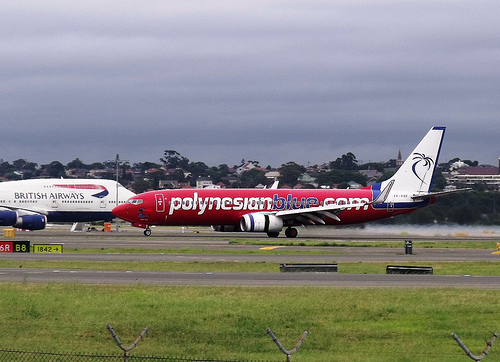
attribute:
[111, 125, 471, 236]
plane — red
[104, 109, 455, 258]
airplane — white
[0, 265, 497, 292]
runway — grassy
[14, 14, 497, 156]
sky — cloudy, overcast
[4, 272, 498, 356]
grass — green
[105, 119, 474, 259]
airplane — white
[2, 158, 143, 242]
airplane — white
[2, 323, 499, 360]
fence — metal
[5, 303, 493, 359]
barbed fence — gray, metal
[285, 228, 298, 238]
tire — black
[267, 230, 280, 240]
tire — black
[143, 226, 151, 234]
tire — black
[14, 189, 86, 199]
lettering — black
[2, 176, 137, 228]
airplane — white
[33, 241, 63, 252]
sign — yellow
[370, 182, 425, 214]
stripe — red, blue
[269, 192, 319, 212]
word — blue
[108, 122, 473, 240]
airplane — red, white, blue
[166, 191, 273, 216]
writing — white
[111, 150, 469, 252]
plane — white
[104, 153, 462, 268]
plane — white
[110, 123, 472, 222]
plane — red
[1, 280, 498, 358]
grass — green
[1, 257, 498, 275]
grass — green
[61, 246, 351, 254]
grass — green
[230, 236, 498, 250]
grass — green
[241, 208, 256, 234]
stripes — black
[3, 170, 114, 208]
plane — white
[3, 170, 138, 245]
plane — large, white, blue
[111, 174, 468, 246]
plane — red, large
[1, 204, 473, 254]
landing strip — gray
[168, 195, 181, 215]
letter — white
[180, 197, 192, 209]
letter — white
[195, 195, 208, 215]
letter — white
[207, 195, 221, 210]
letter — white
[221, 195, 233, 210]
letter — white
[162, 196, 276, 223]
writing — blue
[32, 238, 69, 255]
sign — yellow